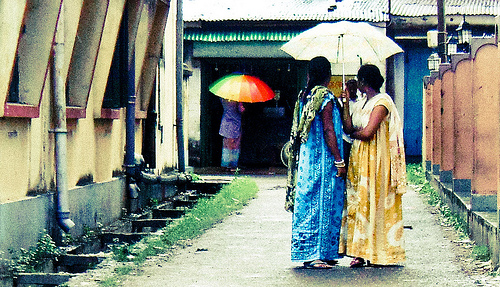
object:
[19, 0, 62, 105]
column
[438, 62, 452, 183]
tan column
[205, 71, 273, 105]
colorful umbrella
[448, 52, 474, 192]
column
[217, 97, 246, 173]
woman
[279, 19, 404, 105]
umbrella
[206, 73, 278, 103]
umbrella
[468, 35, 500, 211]
column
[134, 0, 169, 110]
column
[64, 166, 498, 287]
walkway